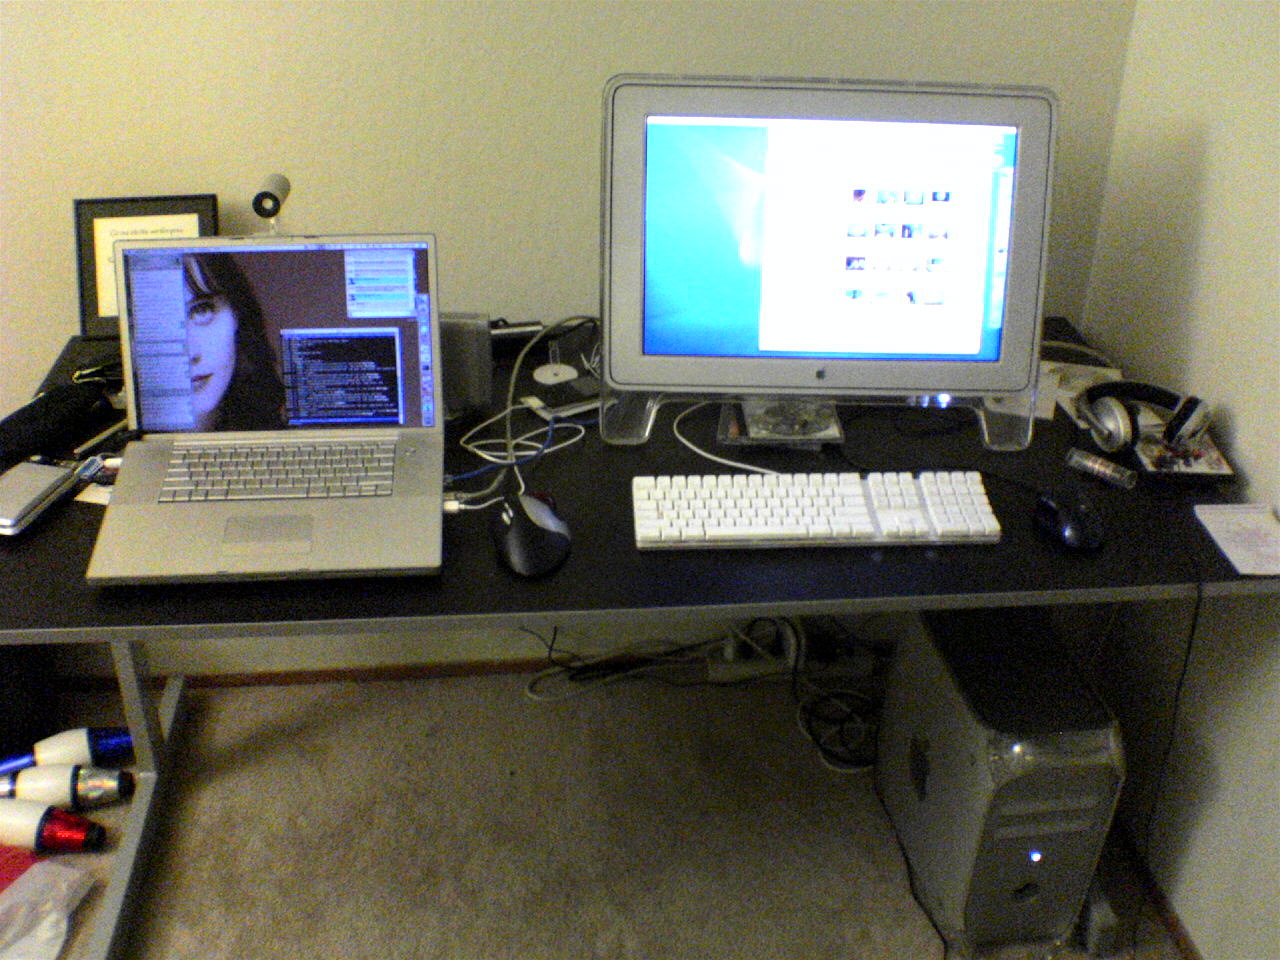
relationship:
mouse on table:
[498, 488, 587, 583] [2, 395, 1263, 643]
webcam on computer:
[233, 170, 309, 237] [93, 182, 472, 591]